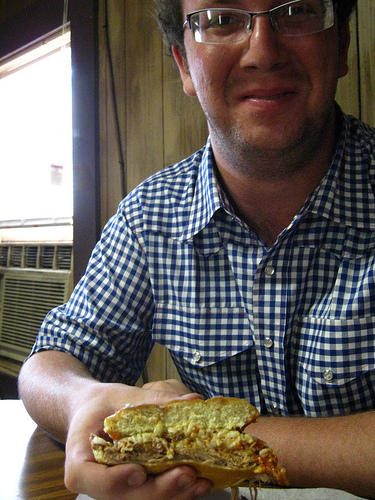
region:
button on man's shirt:
[266, 264, 274, 276]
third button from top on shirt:
[258, 330, 273, 345]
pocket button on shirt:
[191, 341, 197, 357]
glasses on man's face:
[185, 0, 348, 41]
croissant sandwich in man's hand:
[107, 398, 265, 473]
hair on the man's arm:
[330, 427, 358, 464]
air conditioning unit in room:
[3, 237, 72, 328]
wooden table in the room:
[21, 440, 60, 497]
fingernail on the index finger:
[127, 469, 147, 488]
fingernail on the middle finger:
[175, 473, 191, 490]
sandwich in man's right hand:
[91, 390, 289, 498]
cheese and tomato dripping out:
[236, 427, 289, 489]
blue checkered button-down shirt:
[27, 100, 374, 416]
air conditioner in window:
[0, 241, 72, 364]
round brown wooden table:
[1, 397, 82, 498]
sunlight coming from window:
[0, 19, 79, 219]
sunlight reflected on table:
[0, 398, 42, 499]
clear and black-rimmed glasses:
[175, 0, 346, 45]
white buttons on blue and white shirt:
[186, 260, 342, 417]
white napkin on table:
[60, 465, 373, 498]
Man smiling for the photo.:
[148, 1, 358, 170]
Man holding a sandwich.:
[79, 390, 307, 487]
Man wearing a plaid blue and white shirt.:
[33, 154, 372, 424]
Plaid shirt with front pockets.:
[147, 303, 372, 393]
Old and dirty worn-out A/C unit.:
[0, 214, 69, 322]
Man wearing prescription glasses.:
[180, 0, 347, 45]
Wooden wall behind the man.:
[100, 0, 167, 177]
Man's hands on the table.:
[1, 375, 262, 495]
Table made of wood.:
[0, 396, 32, 490]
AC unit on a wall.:
[2, 214, 73, 383]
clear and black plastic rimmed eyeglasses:
[181, 0, 339, 44]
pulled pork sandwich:
[89, 395, 290, 498]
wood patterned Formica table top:
[0, 398, 79, 498]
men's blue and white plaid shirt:
[23, 111, 373, 417]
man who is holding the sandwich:
[17, 0, 374, 498]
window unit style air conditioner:
[0, 236, 75, 364]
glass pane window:
[0, 30, 71, 224]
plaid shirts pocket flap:
[150, 303, 255, 367]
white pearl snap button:
[261, 336, 273, 348]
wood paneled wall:
[97, 0, 373, 390]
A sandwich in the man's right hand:
[98, 399, 284, 483]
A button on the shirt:
[321, 364, 333, 380]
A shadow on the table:
[23, 426, 74, 498]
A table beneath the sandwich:
[0, 397, 317, 498]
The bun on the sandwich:
[104, 397, 252, 429]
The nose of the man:
[243, 21, 285, 68]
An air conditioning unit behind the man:
[0, 241, 72, 366]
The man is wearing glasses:
[184, 1, 334, 40]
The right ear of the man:
[172, 37, 193, 93]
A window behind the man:
[0, 32, 69, 223]